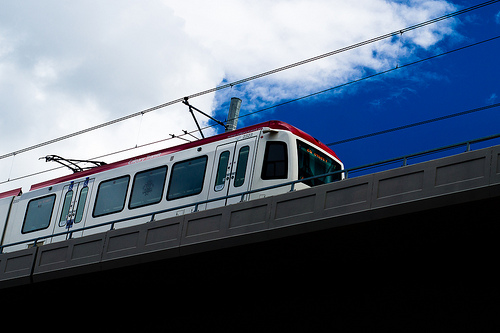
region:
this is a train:
[4, 26, 422, 290]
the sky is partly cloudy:
[77, 10, 202, 90]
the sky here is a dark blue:
[386, 78, 457, 115]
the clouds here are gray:
[35, 25, 195, 113]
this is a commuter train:
[36, 143, 321, 238]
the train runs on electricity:
[120, 105, 331, 181]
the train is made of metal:
[75, 106, 332, 233]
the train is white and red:
[35, 153, 280, 253]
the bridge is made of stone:
[323, 146, 495, 219]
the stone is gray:
[300, 176, 487, 242]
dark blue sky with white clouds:
[3, 3, 493, 153]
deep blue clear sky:
[222, 14, 497, 174]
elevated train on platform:
[4, 114, 356, 256]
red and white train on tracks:
[5, 120, 358, 267]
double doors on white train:
[200, 138, 255, 195]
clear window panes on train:
[92, 150, 221, 216]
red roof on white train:
[7, 115, 356, 203]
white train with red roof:
[0, 122, 351, 267]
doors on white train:
[49, 175, 93, 236]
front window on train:
[293, 140, 350, 191]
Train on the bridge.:
[0, 115, 350, 255]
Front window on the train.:
[290, 135, 340, 190]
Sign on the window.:
[295, 140, 330, 160]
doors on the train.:
[200, 130, 255, 200]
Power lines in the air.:
[0, 0, 495, 180]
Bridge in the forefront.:
[0, 130, 495, 290]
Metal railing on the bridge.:
[2, 130, 499, 259]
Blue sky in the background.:
[204, 0, 496, 178]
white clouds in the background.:
[0, 0, 459, 195]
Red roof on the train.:
[0, 119, 345, 200]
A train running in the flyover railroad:
[17, 155, 360, 226]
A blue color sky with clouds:
[331, 25, 438, 96]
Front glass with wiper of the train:
[298, 145, 347, 188]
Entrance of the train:
[217, 144, 255, 206]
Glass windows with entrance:
[30, 138, 245, 214]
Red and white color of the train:
[146, 121, 326, 205]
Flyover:
[379, 159, 475, 209]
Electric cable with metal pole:
[42, 74, 264, 128]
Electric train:
[45, 154, 131, 188]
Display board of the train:
[303, 143, 336, 163]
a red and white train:
[8, 126, 338, 208]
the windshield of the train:
[298, 142, 339, 182]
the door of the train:
[62, 184, 88, 231]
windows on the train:
[9, 158, 261, 229]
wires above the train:
[16, 35, 469, 132]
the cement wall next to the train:
[11, 153, 492, 289]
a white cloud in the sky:
[23, 16, 213, 109]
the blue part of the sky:
[332, 78, 487, 135]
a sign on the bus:
[301, 148, 353, 168]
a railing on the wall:
[21, 175, 499, 210]